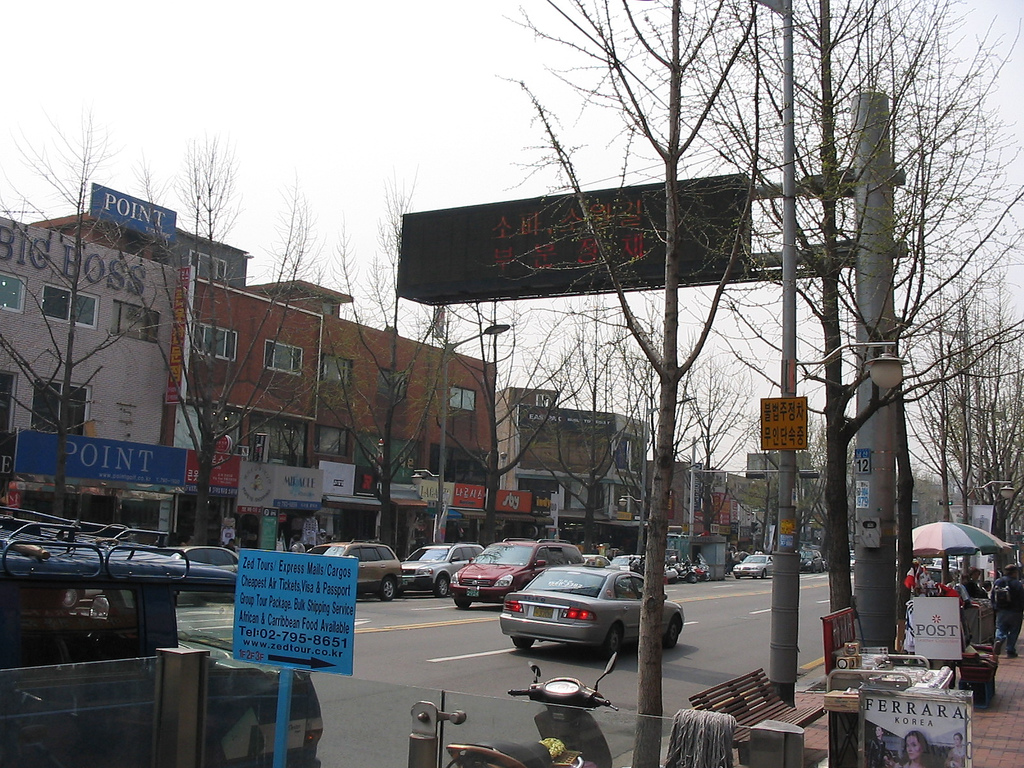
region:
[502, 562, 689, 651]
A gray car on a street.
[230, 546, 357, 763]
A blue sign on a pole.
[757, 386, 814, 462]
A yellow and black sign on a pole.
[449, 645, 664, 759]
A scooter parked by a street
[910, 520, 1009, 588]
A umbrella on a sidewalk.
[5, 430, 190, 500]
A blue and white sign.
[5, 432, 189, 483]
A blue and white sign on a building.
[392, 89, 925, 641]
A red and black sign on a pole.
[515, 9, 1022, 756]
Trees with no leaves.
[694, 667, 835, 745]
A bench on a sidewalk.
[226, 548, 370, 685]
The blue directional sign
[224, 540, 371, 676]
A sign with black words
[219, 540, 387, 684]
The sign with a black arrow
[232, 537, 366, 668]
A sign with a black arrow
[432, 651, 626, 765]
The parked scooter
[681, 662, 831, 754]
The wooden bench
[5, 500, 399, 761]
The parked blue van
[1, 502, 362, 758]
A parked van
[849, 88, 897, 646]
A large pole with a sign on it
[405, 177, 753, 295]
A large sign on a pole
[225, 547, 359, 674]
A blue sign on a post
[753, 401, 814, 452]
An orange sign on a pole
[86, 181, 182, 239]
A blue sign on a roof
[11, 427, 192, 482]
A blue sign on a store front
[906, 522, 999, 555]
An umbrella on a sidewalk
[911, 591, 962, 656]
A white sign on a sidewalk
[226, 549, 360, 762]
light blue sign with black writing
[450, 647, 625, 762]
vespa parked on the curb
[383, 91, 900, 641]
digital sign over the road, hanging from silver pole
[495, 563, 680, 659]
silver car in the road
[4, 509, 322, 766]
blue van with luggage rack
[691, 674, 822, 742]
wooden bench on sidewalk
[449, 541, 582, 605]
red minivan in the road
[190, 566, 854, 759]
a two-way road with traffic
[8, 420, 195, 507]
A blue sign that says Point.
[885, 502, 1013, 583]
A multi colored umbrella.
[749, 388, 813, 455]
A orange sign in a foreign language.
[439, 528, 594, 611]
A red van on the street.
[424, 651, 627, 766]
Part of a parked moped.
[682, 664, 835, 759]
A wooden bench on the sidewalk.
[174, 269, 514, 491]
A red brick building.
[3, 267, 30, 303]
A window on a building.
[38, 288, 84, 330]
A window on a building.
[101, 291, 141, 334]
A window on a building.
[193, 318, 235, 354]
A window on a building.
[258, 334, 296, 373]
A window on a building.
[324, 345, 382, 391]
A window on a building.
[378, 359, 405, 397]
A window on a building.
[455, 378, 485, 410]
A window on a building.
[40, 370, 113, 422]
A window on a building.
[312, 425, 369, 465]
A window on a building.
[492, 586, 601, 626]
Two red rear car lights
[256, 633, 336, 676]
A black arrow pointing to the right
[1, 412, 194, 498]
"POINT" written on blue sign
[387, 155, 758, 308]
A black rectangular sign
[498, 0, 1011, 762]
The trees have no leaves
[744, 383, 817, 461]
Black writing on a yellow sign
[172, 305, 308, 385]
Two windows on a building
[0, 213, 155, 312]
"BIG BOSS" written on building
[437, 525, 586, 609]
A van is red